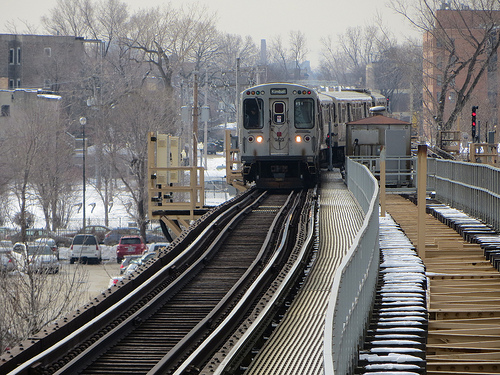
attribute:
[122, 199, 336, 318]
tracks — railing, bare, train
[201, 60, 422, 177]
train — traveling, grey, track, wait, wooden, back, tracks, car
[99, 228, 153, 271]
vehicle — red, parked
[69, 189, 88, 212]
snow — white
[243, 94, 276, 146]
window — train, framed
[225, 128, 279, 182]
light — traffic, train, red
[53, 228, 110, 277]
suv — white, red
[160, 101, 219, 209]
post — wooden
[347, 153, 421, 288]
platform — metal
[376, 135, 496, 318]
walkway — wooden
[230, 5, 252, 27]
sky — grey, cloud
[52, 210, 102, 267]
van — white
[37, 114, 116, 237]
pole — light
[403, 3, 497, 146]
building — large, stairs, tall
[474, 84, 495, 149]
light — red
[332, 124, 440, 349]
fence — metal